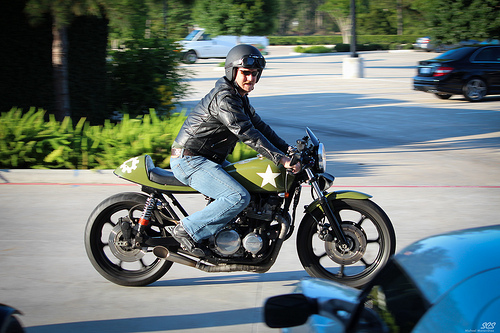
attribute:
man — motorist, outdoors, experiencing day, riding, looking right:
[168, 41, 304, 261]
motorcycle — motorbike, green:
[83, 123, 397, 288]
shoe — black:
[166, 222, 208, 259]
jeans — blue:
[171, 149, 252, 247]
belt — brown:
[169, 147, 202, 158]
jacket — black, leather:
[170, 74, 291, 167]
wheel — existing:
[82, 190, 176, 290]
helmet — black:
[222, 42, 269, 84]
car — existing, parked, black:
[412, 38, 499, 106]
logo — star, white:
[254, 162, 283, 191]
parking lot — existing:
[0, 45, 499, 332]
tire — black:
[461, 76, 490, 103]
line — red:
[0, 179, 499, 190]